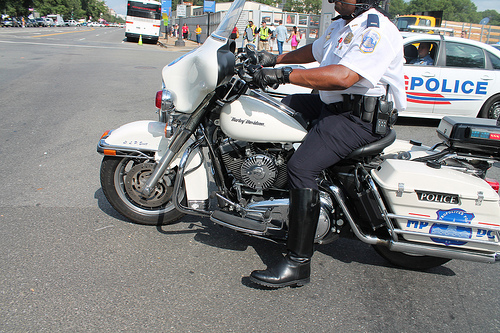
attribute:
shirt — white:
[310, 7, 405, 112]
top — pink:
[288, 30, 301, 44]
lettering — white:
[418, 190, 464, 210]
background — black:
[415, 186, 456, 203]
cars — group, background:
[5, 7, 157, 34]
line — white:
[31, 28, 66, 43]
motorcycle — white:
[82, 8, 484, 279]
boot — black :
[237, 183, 322, 288]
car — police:
[320, 14, 480, 141]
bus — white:
[109, 1, 171, 40]